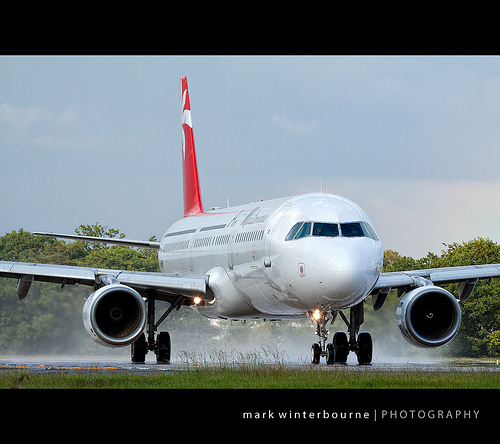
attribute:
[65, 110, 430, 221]
clouds — white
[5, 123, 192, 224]
clouds — white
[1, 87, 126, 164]
clouds — white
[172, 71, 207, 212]
tail — red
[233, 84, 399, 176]
clouds — white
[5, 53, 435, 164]
sky — blue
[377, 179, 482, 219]
clouds — white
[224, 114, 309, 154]
clouds — white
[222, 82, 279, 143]
sky — blue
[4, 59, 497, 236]
sky — blue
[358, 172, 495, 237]
clouds — white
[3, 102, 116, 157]
clouds — white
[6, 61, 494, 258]
clouds — white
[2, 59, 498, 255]
sky — blue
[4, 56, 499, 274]
sky — blue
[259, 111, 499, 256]
clouds — white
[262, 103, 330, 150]
clouds — white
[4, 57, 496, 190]
sky — blue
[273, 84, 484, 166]
clouds — white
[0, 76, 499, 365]
plane — white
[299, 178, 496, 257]
clouds — white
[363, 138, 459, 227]
clouds — white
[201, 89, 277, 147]
sky — blue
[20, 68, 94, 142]
clouds — white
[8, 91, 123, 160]
cloud — white 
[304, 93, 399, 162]
clouds — white